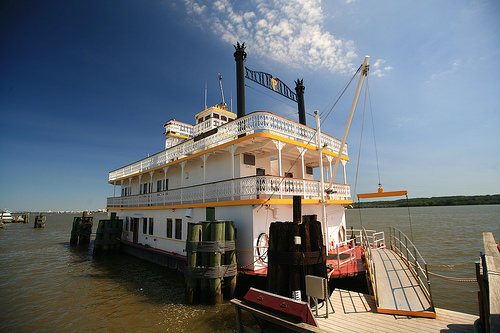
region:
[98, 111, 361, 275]
yellow and white boat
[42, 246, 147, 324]
brown calm water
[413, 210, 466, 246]
brown calm water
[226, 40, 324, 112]
black posts on boat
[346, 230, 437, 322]
tan and gray entrance to boat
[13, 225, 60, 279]
brown calm water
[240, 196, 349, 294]
brown docking tower near boat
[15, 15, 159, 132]
clear blue sky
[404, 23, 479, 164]
blue sky with white clouds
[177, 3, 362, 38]
blue sky with white clouds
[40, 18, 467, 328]
steamboat on a river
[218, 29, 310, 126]
smokestacks on top of steamboat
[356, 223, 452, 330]
gangplank to board steamboat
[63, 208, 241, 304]
large poles to dock to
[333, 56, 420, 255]
pulley system to move gangplank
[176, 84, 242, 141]
pilot house on top of steamboat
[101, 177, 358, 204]
rod iron balcony around steamboat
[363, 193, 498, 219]
shoreline on far side of river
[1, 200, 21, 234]
boat docked further down river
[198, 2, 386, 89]
thin clouds in the sky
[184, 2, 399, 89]
White wispy clouds in the sky.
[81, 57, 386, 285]
One ferry boat at the dock.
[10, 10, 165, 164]
Beautiful, blue sky.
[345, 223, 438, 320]
Bridge from the dock to the boat.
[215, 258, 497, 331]
Wooden dock for loading boats.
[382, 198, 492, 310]
Large body of ocean water.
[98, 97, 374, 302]
Large ferry with yellow trim.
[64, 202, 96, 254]
Cluster of wood poles tied together.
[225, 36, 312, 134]
Decorative archway on the ferry.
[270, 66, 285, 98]
Large letter P in yellow.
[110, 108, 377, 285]
the boat is painted white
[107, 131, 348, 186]
the boat has an orange trim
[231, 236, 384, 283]
the deck is painted red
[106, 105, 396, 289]
the boat is at port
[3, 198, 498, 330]
the sea is calm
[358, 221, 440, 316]
a bridge goes into the boat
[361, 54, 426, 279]
a crane holds up the bridge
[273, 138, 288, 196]
columns hold up the deck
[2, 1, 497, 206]
the sky is blue in color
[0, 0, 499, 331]
the photo was taken outdoors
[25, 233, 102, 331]
water is green and murky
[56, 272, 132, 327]
water is green and murky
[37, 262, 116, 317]
water is green and murky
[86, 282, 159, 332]
water is green and murky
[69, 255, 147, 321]
water is green and murky